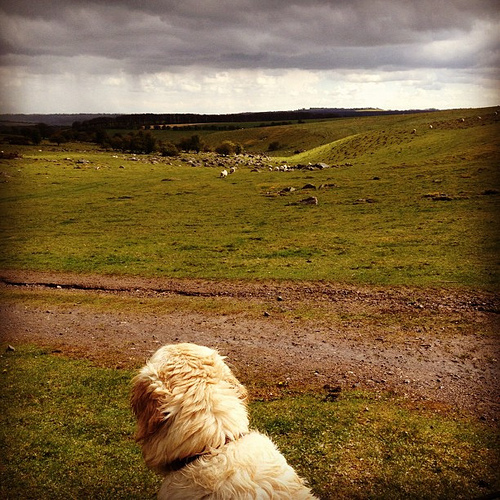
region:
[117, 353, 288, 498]
a yellow dog watching the sheep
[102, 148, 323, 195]
sheep grazing in the field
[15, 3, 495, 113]
the sky with gray clouds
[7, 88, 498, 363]
a hilly country side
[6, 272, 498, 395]
a dirt path in the field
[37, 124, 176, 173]
trees in the distance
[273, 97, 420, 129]
the top of a plateau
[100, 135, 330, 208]
a herd of sheep in the field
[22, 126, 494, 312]
green grassy rolling hills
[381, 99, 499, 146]
sheep grazing down the hill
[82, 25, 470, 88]
a sky with lot of clouds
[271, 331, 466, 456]
dirt with grass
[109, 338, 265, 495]
dog sitting in the grass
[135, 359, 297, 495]
sandle color dog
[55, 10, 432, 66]
black color clouds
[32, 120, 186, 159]
trees with plants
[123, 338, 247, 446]
head of the dog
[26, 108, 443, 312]
dirts, stones and grass in the forest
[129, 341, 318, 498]
A tan dog.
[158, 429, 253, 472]
Black collar on a blonde dog.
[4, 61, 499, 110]
A white line of clouds close to the land.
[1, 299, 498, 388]
Brown path in front of a dog.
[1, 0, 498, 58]
Dark grey clouds in the sky.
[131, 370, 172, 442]
A dogs brown left ear.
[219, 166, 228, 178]
Closest white animal.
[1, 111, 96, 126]
Grey tree line on the far distant left.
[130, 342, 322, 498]
A blonde dog wearing a black collar.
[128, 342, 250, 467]
Head of a yellow dog.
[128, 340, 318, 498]
A dog on the grass.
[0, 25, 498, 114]
A gray cloudy sky.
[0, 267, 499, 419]
A dirt road in the country.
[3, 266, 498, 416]
A dirt country road.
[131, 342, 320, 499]
A dog with a collar.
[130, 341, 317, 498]
The back of a dog.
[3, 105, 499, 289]
Green grassy rolling hills.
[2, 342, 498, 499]
Grass by a road.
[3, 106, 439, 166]
Trees in the background.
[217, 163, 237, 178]
Sheep in the meadow.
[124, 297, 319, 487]
dog has thick fur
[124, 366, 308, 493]
dog has light brown fur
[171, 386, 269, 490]
dog has dark collar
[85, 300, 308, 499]
dog has brown ears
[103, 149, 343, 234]
many sheep in distance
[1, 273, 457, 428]
grey road in front of dog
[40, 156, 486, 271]
soggy green grass across road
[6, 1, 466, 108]
sky is grey and cloudy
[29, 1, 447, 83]
clouds are dark and stormy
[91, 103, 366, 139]
green trees in far distance